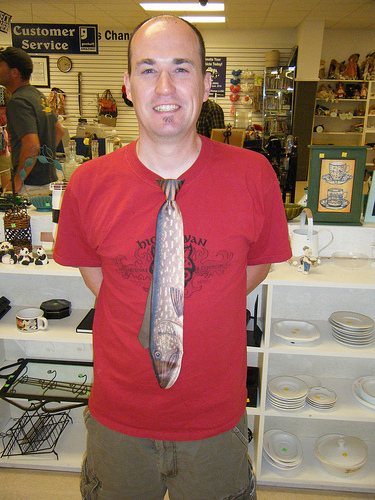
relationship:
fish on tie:
[146, 154, 190, 372] [129, 182, 194, 422]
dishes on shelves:
[268, 287, 351, 466] [253, 246, 375, 499]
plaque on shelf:
[313, 144, 354, 208] [281, 222, 374, 288]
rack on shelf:
[7, 396, 74, 479] [281, 222, 374, 288]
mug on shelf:
[15, 302, 55, 334] [9, 294, 85, 346]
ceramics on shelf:
[7, 235, 61, 269] [3, 230, 92, 280]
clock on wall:
[59, 50, 83, 84] [82, 43, 134, 140]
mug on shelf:
[20, 310, 58, 335] [9, 294, 85, 346]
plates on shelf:
[284, 313, 372, 483] [253, 246, 375, 499]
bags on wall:
[40, 88, 127, 120] [82, 43, 134, 140]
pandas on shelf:
[7, 235, 61, 269] [3, 230, 92, 280]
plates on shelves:
[284, 313, 372, 483] [253, 246, 375, 499]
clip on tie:
[161, 165, 182, 192] [129, 182, 194, 422]